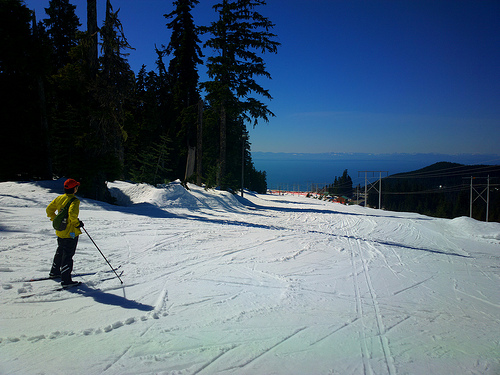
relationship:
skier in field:
[44, 178, 89, 286] [1, 173, 500, 374]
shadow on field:
[107, 197, 471, 262] [1, 173, 500, 374]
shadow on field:
[228, 191, 437, 225] [1, 173, 500, 374]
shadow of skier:
[65, 281, 156, 313] [44, 178, 89, 286]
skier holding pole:
[44, 178, 89, 286] [77, 222, 128, 285]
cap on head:
[63, 178, 80, 188] [61, 177, 81, 195]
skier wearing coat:
[44, 178, 89, 286] [44, 194, 83, 240]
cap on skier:
[63, 178, 80, 188] [44, 178, 89, 286]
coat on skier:
[44, 194, 83, 240] [44, 178, 89, 286]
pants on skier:
[49, 234, 86, 283] [44, 178, 89, 286]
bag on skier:
[49, 196, 78, 235] [44, 178, 89, 286]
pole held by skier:
[77, 222, 128, 285] [44, 178, 89, 286]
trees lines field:
[192, 0, 283, 192] [1, 173, 500, 374]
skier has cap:
[44, 178, 89, 286] [63, 178, 80, 188]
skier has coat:
[44, 178, 89, 286] [44, 194, 83, 240]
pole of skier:
[77, 222, 128, 285] [44, 178, 89, 286]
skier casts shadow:
[44, 178, 89, 286] [65, 281, 156, 313]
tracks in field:
[339, 214, 399, 374] [1, 173, 500, 374]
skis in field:
[16, 261, 126, 291] [1, 173, 500, 374]